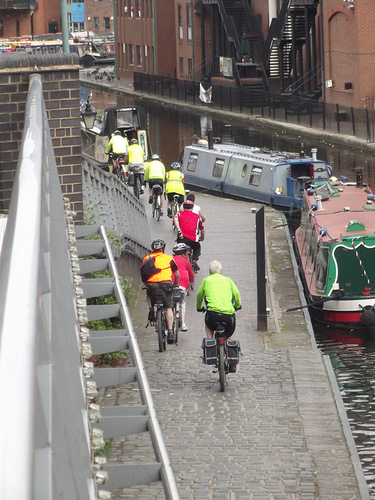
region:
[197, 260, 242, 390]
person on a bike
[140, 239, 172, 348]
person on a bike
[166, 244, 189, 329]
person on a bike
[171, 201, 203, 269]
person on a bike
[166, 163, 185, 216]
person on a bike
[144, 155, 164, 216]
person on a bike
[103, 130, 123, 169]
person on a bike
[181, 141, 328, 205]
blue boat in water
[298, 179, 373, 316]
pink boat in water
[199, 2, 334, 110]
black steps by building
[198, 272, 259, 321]
neon yellow shirt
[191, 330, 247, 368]
bags on the sides of the bike tire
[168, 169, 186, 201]
biker is wearing a safety vest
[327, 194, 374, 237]
pink roof on the boat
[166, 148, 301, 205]
boat is shades of blue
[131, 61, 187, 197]
water between the sidewalks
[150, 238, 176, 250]
man is wearing a black helmet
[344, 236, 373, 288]
candy cane decoration on the back of boat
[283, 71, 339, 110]
stairs on the building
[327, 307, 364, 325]
red stripe on the bottom of boat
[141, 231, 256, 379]
the men are biking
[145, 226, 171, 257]
the helmet is black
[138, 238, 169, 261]
the helmet is black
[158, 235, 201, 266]
the helmet is black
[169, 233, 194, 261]
the helmet is black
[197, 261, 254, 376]
bike rider on street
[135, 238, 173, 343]
bike rider on street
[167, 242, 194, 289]
bike rider on street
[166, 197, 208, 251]
bike rider on street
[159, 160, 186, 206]
bike rider on street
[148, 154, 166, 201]
bike rider on street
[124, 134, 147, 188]
bike rider on street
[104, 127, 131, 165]
bike rider on street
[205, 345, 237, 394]
tire on the bike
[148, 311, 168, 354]
tire on the bike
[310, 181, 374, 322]
red, white and green houseboat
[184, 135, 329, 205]
dark blue and light blue houseboat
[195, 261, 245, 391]
man in lime green jacket and black shorts on bike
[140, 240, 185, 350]
man in orange shirt on bike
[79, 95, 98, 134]
black and white street lantern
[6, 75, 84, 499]
grey steel railing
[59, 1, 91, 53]
green pole with blue sign attached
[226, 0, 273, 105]
black iron staircase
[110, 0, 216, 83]
red brick building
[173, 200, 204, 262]
man in red shirt on bike